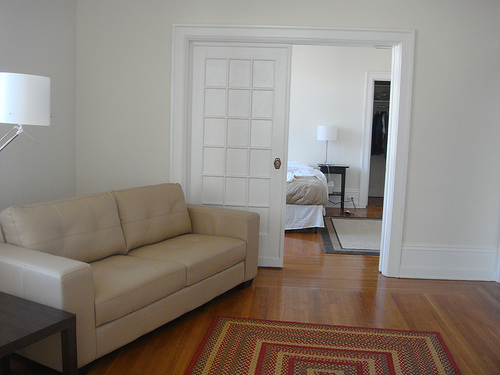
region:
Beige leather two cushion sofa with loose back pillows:
[4, 178, 261, 372]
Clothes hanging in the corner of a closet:
[368, 81, 389, 208]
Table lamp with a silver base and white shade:
[314, 123, 339, 167]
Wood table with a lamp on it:
[316, 123, 362, 211]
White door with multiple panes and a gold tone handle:
[173, 23, 418, 274]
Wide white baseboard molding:
[380, 242, 496, 277]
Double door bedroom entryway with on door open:
[175, 25, 418, 275]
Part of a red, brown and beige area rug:
[181, 310, 466, 370]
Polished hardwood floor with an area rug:
[91, 273, 496, 372]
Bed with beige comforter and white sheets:
[288, 161, 328, 233]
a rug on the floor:
[296, 292, 421, 360]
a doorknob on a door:
[268, 150, 282, 175]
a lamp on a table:
[316, 115, 337, 166]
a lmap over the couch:
[4, 62, 61, 152]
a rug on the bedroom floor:
[306, 224, 360, 268]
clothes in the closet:
[369, 87, 392, 155]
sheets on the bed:
[285, 150, 324, 213]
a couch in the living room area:
[121, 210, 246, 333]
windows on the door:
[203, 48, 275, 157]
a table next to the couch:
[9, 285, 64, 374]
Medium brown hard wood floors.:
[290, 258, 363, 324]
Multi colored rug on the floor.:
[200, 328, 446, 373]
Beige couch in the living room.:
[10, 178, 274, 333]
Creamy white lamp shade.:
[0, 60, 60, 140]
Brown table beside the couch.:
[1, 275, 74, 370]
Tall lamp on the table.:
[305, 118, 352, 165]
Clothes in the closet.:
[359, 77, 391, 174]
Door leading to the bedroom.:
[178, 36, 311, 205]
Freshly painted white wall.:
[413, 35, 479, 235]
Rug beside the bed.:
[305, 207, 379, 262]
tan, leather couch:
[7, 185, 260, 359]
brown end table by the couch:
[2, 297, 75, 369]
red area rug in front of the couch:
[186, 315, 461, 372]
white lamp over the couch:
[0, 73, 52, 150]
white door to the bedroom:
[194, 45, 289, 266]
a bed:
[289, 165, 326, 230]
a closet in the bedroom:
[367, 83, 386, 210]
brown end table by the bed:
[320, 163, 347, 213]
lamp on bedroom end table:
[320, 124, 338, 159]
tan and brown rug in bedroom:
[322, 214, 382, 253]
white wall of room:
[0, 1, 498, 276]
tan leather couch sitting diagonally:
[0, 180, 260, 372]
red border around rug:
[186, 314, 463, 374]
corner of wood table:
[0, 289, 77, 372]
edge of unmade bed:
[287, 162, 326, 228]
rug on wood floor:
[322, 216, 386, 253]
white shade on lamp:
[316, 124, 337, 166]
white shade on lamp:
[1, 72, 51, 149]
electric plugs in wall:
[328, 167, 357, 211]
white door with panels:
[186, 40, 291, 268]